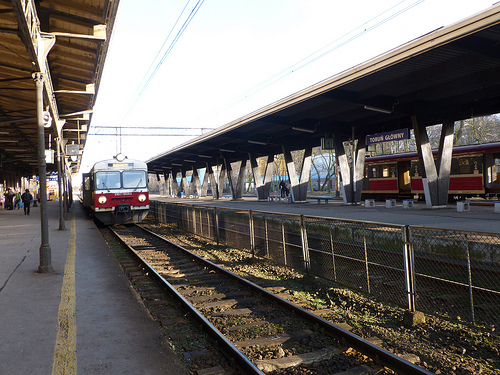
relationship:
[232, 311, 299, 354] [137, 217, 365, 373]
gravel on tracks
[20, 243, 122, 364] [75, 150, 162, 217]
platform beside train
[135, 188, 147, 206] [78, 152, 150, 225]
light on train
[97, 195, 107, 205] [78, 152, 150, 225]
headlights on train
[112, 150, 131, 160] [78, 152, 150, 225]
light on train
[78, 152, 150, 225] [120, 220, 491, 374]
train on tracks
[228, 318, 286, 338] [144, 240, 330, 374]
rocks on track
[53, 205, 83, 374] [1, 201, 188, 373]
line on ground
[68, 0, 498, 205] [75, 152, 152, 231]
sky above train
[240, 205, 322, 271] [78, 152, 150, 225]
fence next train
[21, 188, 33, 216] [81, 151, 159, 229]
commuters next train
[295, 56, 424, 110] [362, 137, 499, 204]
structure above train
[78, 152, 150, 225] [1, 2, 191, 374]
train in station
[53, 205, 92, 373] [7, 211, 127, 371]
line on sidewalk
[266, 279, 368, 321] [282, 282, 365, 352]
grass on ground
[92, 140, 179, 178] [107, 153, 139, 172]
sign showing destination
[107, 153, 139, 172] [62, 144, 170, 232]
destination of train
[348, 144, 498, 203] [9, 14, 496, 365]
train leaving city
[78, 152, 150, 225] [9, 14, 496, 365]
train leaving city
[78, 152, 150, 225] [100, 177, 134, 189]
train carrying commuters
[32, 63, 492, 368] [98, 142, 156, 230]
train on schedule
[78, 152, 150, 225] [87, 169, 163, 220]
train running late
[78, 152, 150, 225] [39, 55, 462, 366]
train going to suburbs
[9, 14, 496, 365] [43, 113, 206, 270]
city operates train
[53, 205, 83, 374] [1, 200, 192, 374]
line on sidewalk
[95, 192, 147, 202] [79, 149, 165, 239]
headlights on train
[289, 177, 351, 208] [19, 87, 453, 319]
bench in terminal